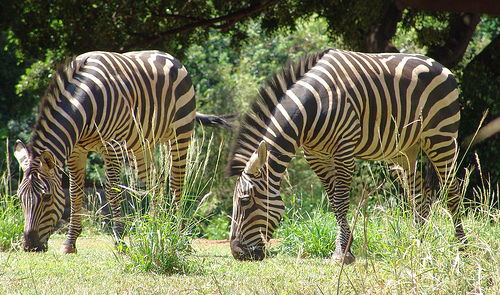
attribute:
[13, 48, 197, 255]
zebra — grazing, black, white, eating, stripped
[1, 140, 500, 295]
grass — short, long, growing, tall, green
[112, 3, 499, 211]
tree — brown, growing, green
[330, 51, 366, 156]
stripe — black, white